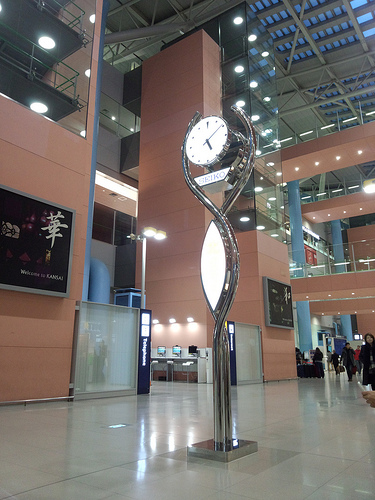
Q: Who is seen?
A: People visiting in the mall.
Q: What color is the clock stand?
A: Silver.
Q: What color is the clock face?
A: White.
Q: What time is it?
A: 5:10.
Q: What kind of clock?
A: Seiko.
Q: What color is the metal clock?
A: Chrome.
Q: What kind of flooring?
A: Tile.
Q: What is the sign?
A: Advertising.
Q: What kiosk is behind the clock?
A: Computers.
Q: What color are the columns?
A: Blue.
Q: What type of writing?
A: Japanese.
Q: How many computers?
A: Three.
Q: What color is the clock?
A: White and black.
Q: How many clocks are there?
A: One.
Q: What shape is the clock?
A: Circle.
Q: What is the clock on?
A: A pole.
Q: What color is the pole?
A: Silver.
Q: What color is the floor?
A: Gray.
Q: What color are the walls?
A: Brown.